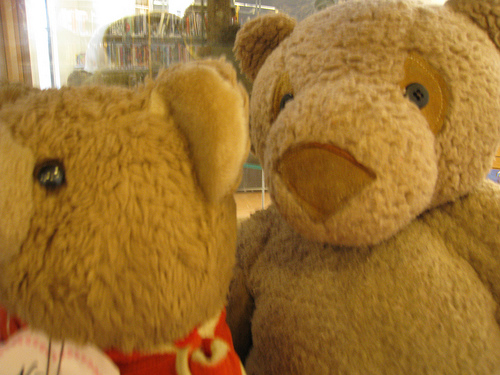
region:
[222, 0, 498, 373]
a fur brown bear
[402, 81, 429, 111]
a bear with button eye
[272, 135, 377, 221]
a bear with a brown mouth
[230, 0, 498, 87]
a bear with two brown ears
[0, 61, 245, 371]
a small brown bear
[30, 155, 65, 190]
a bear with a black eye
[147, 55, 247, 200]
a bear with a large brown ear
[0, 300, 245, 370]
a bear with yellow and top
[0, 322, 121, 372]
white and pink design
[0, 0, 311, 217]
back ground with many colors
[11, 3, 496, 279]
two teddy bears by a window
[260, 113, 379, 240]
a nose shaped like a pie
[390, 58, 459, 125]
a black button used for an eye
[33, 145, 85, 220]
One shiny dark plastic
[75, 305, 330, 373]
Red and yellow striped shirt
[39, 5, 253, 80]
Books on shelves in next room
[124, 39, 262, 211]
One teddy bear ear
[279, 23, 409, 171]
Old matted teddy bear fur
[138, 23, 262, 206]
lighter fur inside ear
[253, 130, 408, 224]
This could be a large mouth on bears snout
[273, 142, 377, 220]
brown nose on stuffed bear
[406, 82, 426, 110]
blue button eye of bear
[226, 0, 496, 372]
brown bear with no clothes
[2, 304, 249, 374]
bear wearing red outfit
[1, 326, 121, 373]
white patch on front of outfit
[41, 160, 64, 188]
black eye of bear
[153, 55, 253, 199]
right ear of bear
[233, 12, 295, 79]
left ear of bear in back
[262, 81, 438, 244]
long nose and mouth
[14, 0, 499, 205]
window behind bears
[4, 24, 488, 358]
two teddy bears in photo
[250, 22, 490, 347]
teddy bear on right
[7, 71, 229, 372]
teddy bear on left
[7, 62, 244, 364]
teddy bear in red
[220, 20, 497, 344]
bear with upside triangle nose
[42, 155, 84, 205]
bear with black round eyes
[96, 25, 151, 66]
multicolored books on shelves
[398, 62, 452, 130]
bear with button eyes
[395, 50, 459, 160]
button eyes and patches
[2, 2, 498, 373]
Two brown teddy bears.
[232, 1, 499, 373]
Brown teddy bear beside another teddy bear.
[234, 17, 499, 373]
Teddy bear with black button eyes.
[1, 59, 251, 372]
Dressed brown teddy with black eyes.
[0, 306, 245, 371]
Shirt on brown teddy bear.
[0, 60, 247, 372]
Brown dressed teddy bear beside another teddy bear.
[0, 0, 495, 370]
Two brown teddy bears in front of a window.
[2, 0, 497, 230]
Glass window behind teddy bears.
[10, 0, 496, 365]
Bookstore behind two brown teddy bears.